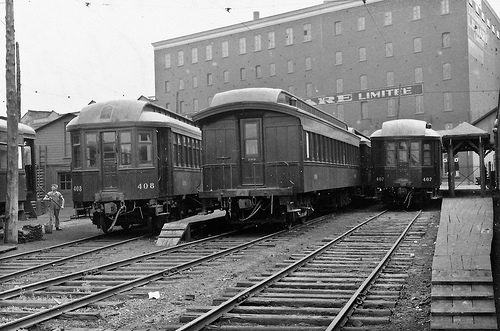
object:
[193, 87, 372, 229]
cars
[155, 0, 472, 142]
wall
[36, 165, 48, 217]
stick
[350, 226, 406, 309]
metal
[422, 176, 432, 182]
407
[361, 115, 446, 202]
train car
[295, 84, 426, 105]
sign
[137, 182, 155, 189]
408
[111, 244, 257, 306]
dirt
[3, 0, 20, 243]
pole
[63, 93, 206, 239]
train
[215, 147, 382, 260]
ground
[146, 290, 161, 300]
paper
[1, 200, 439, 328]
ground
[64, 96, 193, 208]
train car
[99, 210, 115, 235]
wheels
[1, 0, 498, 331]
photo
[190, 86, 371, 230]
container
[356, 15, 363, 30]
window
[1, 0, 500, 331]
taken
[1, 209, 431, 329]
train tracks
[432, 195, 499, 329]
staircase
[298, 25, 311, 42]
window pane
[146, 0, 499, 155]
building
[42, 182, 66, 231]
man